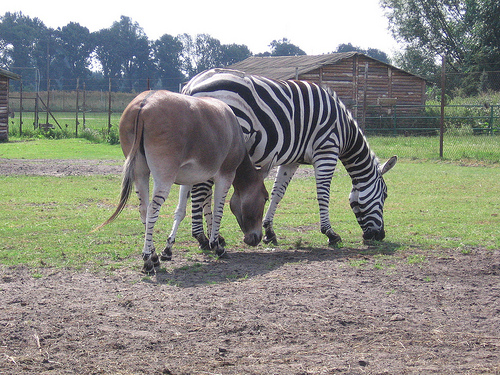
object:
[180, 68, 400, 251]
zebra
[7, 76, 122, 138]
fence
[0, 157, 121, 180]
patch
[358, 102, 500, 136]
fence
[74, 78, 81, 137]
wood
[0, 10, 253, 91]
tree line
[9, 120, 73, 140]
flowers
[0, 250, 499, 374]
dirt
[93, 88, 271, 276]
donkey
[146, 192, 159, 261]
stripe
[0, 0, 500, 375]
scenario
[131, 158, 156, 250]
leg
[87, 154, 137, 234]
hair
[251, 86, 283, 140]
stripes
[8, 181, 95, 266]
grass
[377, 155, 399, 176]
ear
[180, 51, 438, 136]
barn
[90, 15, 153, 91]
tree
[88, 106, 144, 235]
tail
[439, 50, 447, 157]
post